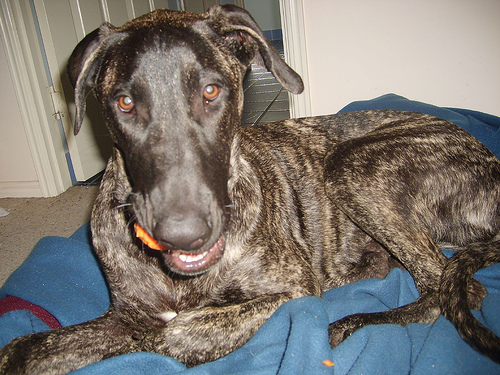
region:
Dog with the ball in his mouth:
[108, 209, 232, 274]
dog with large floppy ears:
[43, 18, 320, 135]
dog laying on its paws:
[63, 274, 271, 373]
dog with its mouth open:
[153, 213, 238, 280]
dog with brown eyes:
[106, 83, 233, 118]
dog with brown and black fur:
[274, 136, 450, 228]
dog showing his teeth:
[176, 254, 206, 264]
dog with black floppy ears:
[56, 4, 126, 136]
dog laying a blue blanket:
[318, 79, 481, 337]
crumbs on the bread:
[313, 349, 348, 374]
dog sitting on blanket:
[27, 4, 491, 372]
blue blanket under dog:
[28, 100, 498, 354]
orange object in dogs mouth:
[122, 223, 167, 253]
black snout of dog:
[111, 130, 226, 268]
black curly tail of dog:
[435, 217, 497, 372]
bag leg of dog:
[330, 120, 487, 340]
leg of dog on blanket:
[5, 287, 245, 370]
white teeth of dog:
[178, 244, 209, 262]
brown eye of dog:
[198, 83, 217, 98]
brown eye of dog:
[113, 88, 130, 112]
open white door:
[30, 0, 165, 180]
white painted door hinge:
[44, 83, 64, 119]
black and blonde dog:
[2, 2, 499, 373]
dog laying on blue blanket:
[7, 2, 495, 369]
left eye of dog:
[115, 90, 131, 107]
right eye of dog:
[202, 77, 219, 97]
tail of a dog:
[442, 238, 498, 360]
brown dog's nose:
[155, 219, 211, 252]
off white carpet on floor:
[1, 185, 102, 310]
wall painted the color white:
[1, 3, 496, 178]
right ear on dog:
[201, 2, 278, 67]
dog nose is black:
[166, 218, 204, 245]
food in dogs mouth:
[136, 226, 154, 249]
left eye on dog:
[109, 83, 139, 125]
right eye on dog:
[193, 71, 228, 112]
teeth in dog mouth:
[181, 252, 205, 263]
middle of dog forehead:
[142, 53, 179, 78]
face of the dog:
[73, 34, 274, 324]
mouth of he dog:
[153, 211, 263, 299]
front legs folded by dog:
[116, 306, 251, 368]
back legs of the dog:
[392, 218, 457, 278]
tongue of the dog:
[118, 223, 165, 260]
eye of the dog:
[183, 61, 239, 121]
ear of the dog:
[219, 16, 329, 110]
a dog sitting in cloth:
[83, 46, 446, 333]